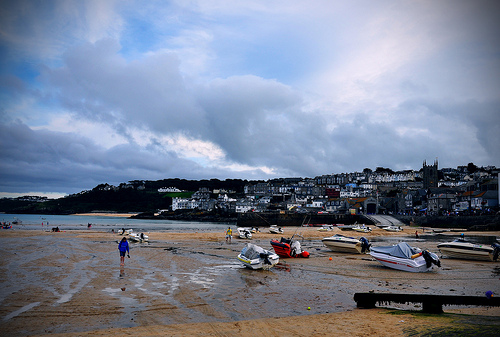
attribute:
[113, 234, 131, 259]
person — walking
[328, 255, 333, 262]
roundobject — round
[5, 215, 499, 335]
sandy beach — small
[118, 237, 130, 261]
woman — standing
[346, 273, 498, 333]
bench — small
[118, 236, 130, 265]
woman — walking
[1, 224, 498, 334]
shore — sandy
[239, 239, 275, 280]
boats — parking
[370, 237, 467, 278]
boat — white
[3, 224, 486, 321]
sand — covered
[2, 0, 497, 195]
clouds — above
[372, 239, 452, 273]
boat — covered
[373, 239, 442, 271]
boat — red